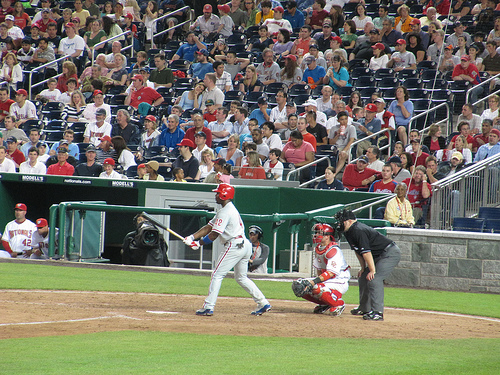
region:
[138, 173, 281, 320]
batter holding bat over plate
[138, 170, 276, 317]
batter wearing red helmet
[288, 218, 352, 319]
catcher crouching on ground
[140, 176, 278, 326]
batter is black and wearing white uniform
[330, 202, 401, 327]
umpire standing with hands on knees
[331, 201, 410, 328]
umpire wearing black helmet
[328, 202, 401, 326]
umpire wearing black shirt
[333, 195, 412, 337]
umpire wearing black shoes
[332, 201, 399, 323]
umpire wearing gray pants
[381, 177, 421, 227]
bald man standing behind mound in yellow shirt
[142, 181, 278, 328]
Batter up waits hit baseball.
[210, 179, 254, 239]
Wear red safety helmet.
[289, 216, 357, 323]
Catcher scrunched down baseball.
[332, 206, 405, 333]
Umpire behind catcher home base.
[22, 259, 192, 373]
Home dirt base white patch.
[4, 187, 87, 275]
Dugout players await turn.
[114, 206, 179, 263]
Sports cameraman takes pictures.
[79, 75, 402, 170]
Spectator bleacher seats occupied.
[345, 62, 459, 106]
Only few empty bleacher seats.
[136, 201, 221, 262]
Batter firm grip baseball bat.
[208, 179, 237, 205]
Red baseball helmet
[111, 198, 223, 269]
Brown and black baseball bat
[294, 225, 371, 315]
Catcher kneeling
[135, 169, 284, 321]
Baseball player wearing red and white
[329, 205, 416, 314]
Umpire wearing black and gray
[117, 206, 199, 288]
Video camera pointed at the players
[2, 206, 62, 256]
Men waiting to play baseball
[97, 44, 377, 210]
Fans watching a baseball game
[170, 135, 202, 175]
Man in a black shirt and red hat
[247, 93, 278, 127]
Man in a blue shirt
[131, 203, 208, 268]
wooden baseball bat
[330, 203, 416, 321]
umpire wearing all black uniform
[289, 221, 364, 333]
hind catcher wearing red and white uniform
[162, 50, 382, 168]
crowd watching ball game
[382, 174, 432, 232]
security guard sitting in chair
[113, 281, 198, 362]
home late on a ball field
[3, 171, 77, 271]
ball players in dug out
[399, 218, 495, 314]
gray stone divider wall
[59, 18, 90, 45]
man wearing red hat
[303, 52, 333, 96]
man wearing blue shirt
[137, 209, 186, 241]
a black and brown wooden baseball bat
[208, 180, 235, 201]
a red batting helmet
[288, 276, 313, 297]
a black baseball mitt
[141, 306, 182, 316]
a white home plate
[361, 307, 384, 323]
a black shoe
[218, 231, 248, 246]
a red belt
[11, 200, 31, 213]
a red baseball cap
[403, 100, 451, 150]
a silver metal railing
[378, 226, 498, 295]
a gray stone wall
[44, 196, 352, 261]
a green padded railing